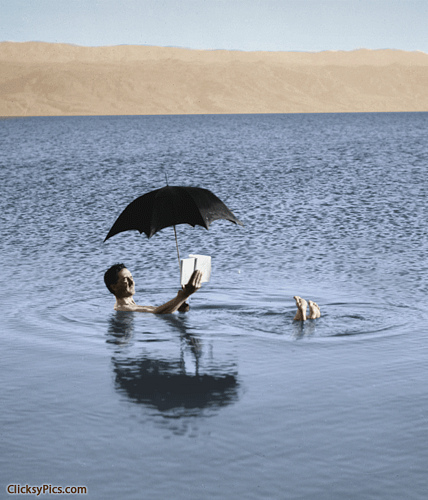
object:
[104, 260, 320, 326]
person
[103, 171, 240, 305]
umbrella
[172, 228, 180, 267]
pole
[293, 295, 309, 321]
feet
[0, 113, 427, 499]
water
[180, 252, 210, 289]
book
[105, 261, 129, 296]
hair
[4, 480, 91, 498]
clicksypics.com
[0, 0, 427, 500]
image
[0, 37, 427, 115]
sand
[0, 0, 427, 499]
background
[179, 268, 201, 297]
right hand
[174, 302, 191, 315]
left hand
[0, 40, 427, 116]
mountains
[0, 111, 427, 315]
ripple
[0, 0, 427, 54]
sky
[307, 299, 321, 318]
foot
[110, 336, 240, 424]
reflection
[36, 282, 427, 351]
ripple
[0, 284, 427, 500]
light